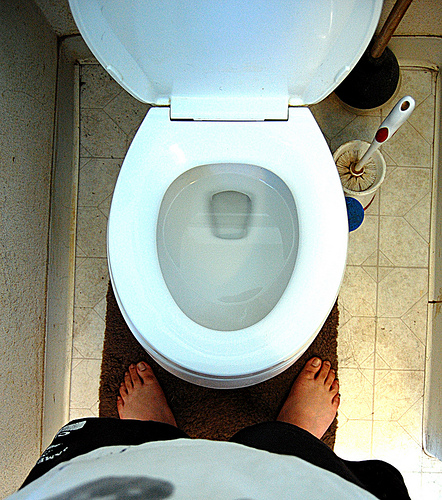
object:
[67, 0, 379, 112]
lid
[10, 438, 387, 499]
shirt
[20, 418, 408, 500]
shorts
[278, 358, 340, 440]
feet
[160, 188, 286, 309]
water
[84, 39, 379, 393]
toilet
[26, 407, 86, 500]
white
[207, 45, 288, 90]
up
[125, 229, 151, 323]
white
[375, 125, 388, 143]
red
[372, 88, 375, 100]
brown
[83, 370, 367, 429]
visible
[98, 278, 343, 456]
rug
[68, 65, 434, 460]
floor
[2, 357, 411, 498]
person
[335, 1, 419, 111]
plunger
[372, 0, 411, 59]
handle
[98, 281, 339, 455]
bathroom carpet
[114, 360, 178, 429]
left foot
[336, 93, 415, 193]
toilet brush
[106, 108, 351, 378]
toilet seat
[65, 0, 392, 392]
white toilet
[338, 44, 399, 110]
rubber plunger